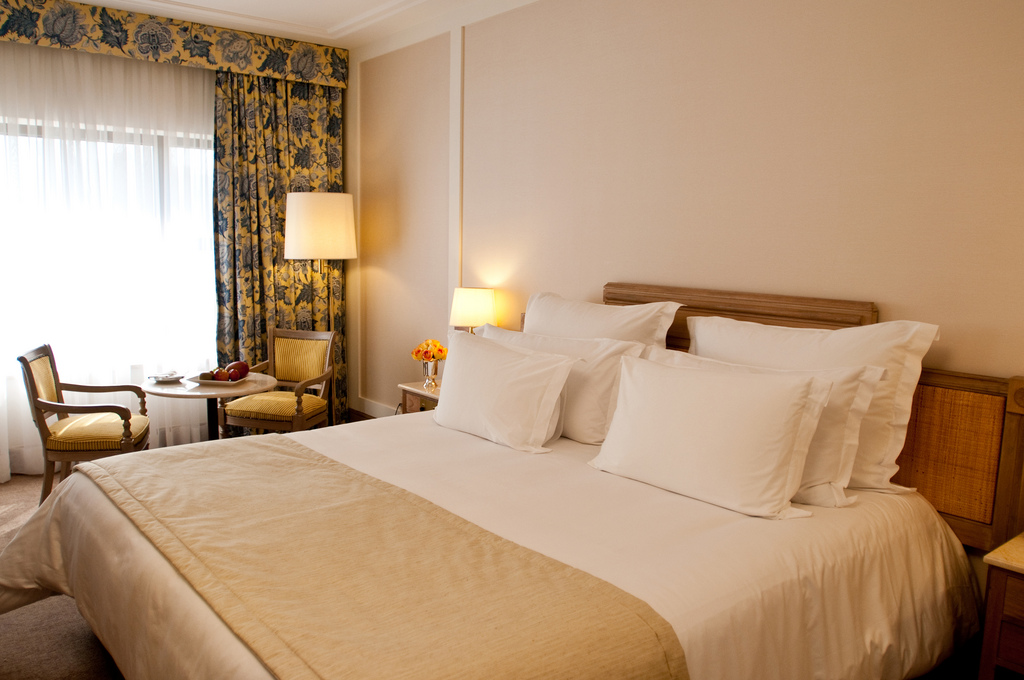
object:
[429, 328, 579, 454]
pillow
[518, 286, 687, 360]
pillow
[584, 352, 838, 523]
pillow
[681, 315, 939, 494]
pillow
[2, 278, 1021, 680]
bed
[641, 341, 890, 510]
pillow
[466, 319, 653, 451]
pillow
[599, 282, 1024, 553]
head board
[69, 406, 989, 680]
coverlet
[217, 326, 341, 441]
chairs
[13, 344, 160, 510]
chair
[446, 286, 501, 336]
nightstand lamp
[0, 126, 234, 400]
window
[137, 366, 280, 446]
table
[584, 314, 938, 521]
three pillows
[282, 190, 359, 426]
lamp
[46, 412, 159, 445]
cushion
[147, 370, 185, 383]
objects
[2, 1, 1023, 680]
hotel room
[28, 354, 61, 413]
upholstery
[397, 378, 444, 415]
table